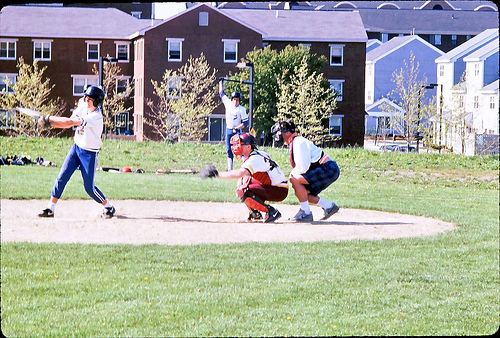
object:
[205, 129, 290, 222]
kids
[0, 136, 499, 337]
field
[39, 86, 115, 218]
kid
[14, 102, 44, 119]
bat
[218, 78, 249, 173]
kid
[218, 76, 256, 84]
bat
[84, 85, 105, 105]
helmet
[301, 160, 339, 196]
shorts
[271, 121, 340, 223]
umpire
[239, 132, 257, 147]
helmet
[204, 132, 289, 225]
catcher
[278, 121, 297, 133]
helmet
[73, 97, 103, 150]
shirt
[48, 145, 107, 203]
pants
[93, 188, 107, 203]
stripes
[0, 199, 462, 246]
sand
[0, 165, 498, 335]
grass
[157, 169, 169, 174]
supplies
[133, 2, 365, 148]
building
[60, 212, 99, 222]
plate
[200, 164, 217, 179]
glove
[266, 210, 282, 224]
shoes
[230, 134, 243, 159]
mask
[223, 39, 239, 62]
window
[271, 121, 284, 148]
mask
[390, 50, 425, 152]
tree